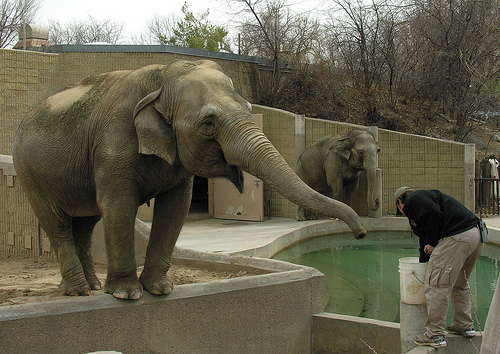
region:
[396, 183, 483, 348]
A man reaching into a bucket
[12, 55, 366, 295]
An elephant extending its truck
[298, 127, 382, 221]
An elephant standing by a pool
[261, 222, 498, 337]
A pool with stairs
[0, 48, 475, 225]
A wall in the background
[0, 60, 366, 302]
An elephant standing on dirt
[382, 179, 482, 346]
man wearing black shirt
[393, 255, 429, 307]
white bucket next to man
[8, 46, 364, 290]
elephant next to man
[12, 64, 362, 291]
elephant reaching his trunk out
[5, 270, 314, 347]
ledge elephant is standing on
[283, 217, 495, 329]
pool of green water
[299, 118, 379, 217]
elephant standing beside cement wall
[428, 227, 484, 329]
khaki pants man is wearing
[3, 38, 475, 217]
cement block building behind the elephants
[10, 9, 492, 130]
trees behind the building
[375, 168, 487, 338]
man wearing black sweatshirt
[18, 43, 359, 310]
elephant standing in the dirt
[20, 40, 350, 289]
elephant has it's trunk out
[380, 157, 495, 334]
man digging in a white bucket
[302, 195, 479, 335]
pool for elephants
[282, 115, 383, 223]
elephant standing next to the wall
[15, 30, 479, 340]
elephant exhibit at the zoo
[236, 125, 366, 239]
Gray elephant trunk pointed at a man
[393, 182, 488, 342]
Man bent over the water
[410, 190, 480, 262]
Black coat on a man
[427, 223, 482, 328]
Tan pants on a man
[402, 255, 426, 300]
White bucket on a post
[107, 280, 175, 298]
Front feet on an elephant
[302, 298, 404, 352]
Cement divider in water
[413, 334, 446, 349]
Shoe on man's foot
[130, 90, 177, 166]
Floppy gray ear on elephant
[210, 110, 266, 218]
Tan door in wall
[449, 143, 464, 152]
yellow brick on wall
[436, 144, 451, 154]
yellow brick on wall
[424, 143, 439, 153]
yellow brick on wall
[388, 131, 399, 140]
yellow brick on wall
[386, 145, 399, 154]
yellow brick on wall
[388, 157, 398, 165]
yellow brick on wall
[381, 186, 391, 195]
yellow brick on wall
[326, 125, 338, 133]
yellow brick on wall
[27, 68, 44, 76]
yellow brick on wall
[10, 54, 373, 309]
large elephant with outstretched trunk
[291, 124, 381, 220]
elephant in background near wall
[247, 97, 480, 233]
stone wall behind elephant on right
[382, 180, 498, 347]
man in black jacket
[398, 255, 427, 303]
a large white bucket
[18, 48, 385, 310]
an elephant that is standing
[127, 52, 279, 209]
the face of an elephant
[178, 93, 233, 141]
the eye of an elephant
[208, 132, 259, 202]
the mouth of an elephant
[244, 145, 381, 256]
the trunk of an elephant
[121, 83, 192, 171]
the ear of an elephant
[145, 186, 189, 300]
the left leg of an elephant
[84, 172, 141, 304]
the right leg of an elephant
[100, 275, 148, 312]
the toes of an elephant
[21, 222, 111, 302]
the back legs of an elephant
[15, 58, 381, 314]
grey elephant in zoo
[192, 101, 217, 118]
right eye of the elephant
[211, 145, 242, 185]
mouth of the elephant